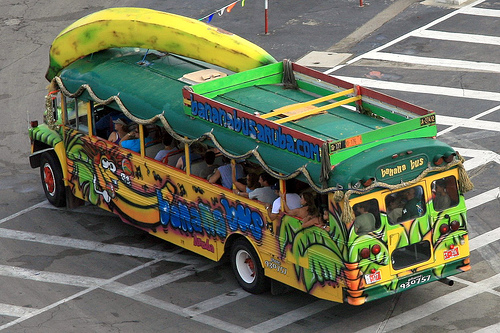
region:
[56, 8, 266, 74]
yellow and green banana on bus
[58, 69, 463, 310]
multi colored passenger bus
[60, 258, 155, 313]
white lines in gray pavement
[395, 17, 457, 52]
white lines in gray pavement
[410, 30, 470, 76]
white lines in gray pavement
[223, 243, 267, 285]
black and white tire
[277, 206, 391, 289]
palm tree leaves with black outline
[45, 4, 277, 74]
large yellow and green banana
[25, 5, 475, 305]
yellow bus with decorative paint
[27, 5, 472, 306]
bus with a yellow banana on top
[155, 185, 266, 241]
blue letters outlined in black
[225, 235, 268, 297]
black tire with white rim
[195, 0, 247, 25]
pennant of hanging flags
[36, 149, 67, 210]
black tire with red center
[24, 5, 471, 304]
yellow bus with green roof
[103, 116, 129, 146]
woman wearing a sun visor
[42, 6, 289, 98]
big banana on top of bus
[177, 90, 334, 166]
bananabusaruba.com logo in blue print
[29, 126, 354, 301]
side panel design for the banana bus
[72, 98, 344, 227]
tourists inside of the banana bus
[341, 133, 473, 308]
design on rear panel on banana bus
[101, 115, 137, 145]
tourist looking outside of window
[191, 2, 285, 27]
line holding flags of different colors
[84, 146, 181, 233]
banana designed with eyes and hands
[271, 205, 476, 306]
design of palm trees on back of bus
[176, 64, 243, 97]
fire escape on top of bus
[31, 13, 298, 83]
A giant banana on a bus.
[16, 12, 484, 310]
A large school bus.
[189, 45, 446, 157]
A rack on top of a bus.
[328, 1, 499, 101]
Lines painted on a street.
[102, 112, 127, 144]
A woman wearing a visor.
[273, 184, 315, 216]
A woman with her arm outside a bus.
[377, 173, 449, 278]
A door on a bus.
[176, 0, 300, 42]
Flags on a string.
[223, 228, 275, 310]
Back tire of a bus.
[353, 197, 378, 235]
a bus rear window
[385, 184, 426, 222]
a bus rear window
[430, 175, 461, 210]
a bus rear window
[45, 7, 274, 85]
a large figural banana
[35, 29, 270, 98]
A big banana on top of the bus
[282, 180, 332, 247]
People looking out a window of a bus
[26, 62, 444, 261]
Crazy looking bus with lots of people in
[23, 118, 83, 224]
A tire with red ran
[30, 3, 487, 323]
a festive bus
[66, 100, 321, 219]
people inside of bus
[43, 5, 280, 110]
a large banana on bus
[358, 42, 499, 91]
white line on pavement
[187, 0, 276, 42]
a multicolored banner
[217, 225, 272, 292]
a black wheel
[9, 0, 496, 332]
a scene outside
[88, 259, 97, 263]
a piece of the image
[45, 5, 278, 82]
large yellow and green banana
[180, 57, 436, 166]
painted wood box on top of bus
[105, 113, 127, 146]
woman wearing beige visor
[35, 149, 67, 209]
black tire with red middle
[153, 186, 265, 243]
banana bus graffiti painted in blue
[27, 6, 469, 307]
yellow bus with a large banana on top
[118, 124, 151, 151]
person inside bus wearing blue shirt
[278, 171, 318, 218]
woman holding onto bus frame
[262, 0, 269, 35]
red and white pole